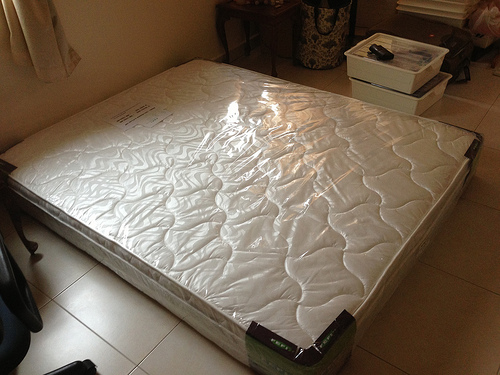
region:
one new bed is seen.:
[110, 125, 310, 238]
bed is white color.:
[160, 150, 315, 255]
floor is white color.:
[420, 290, 485, 340]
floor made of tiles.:
[46, 285, 126, 360]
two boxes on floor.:
[340, 36, 432, 109]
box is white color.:
[347, 40, 447, 105]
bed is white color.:
[166, 195, 341, 275]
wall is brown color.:
[85, 25, 165, 80]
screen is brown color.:
[11, 12, 54, 68]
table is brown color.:
[216, 23, 323, 62]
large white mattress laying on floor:
[65, 56, 475, 349]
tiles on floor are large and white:
[55, 266, 195, 364]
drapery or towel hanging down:
[0, 4, 106, 96]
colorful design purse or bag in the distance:
[289, 1, 358, 80]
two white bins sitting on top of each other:
[334, 27, 463, 126]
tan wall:
[49, 16, 145, 72]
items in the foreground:
[0, 266, 122, 369]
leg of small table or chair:
[7, 179, 76, 281]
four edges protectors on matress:
[202, 311, 385, 365]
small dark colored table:
[200, 4, 299, 79]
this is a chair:
[1, 247, 79, 372]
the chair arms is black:
[0, 235, 96, 373]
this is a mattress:
[17, 77, 471, 302]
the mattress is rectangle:
[61, 48, 426, 339]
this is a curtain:
[2, 1, 90, 80]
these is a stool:
[222, 2, 300, 67]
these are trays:
[344, 32, 462, 99]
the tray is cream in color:
[337, 35, 454, 95]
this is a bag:
[363, 10, 493, 52]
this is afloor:
[393, 285, 498, 367]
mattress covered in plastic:
[35, 61, 498, 318]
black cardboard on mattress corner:
[245, 306, 362, 371]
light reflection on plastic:
[217, 96, 286, 142]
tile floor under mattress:
[71, 258, 124, 333]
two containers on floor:
[344, 32, 460, 123]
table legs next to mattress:
[210, 9, 298, 73]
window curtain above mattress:
[25, 10, 77, 92]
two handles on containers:
[425, 57, 450, 99]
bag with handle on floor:
[285, 4, 353, 74]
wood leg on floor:
[7, 204, 44, 264]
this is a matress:
[56, 132, 384, 234]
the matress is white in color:
[43, 150, 423, 237]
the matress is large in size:
[58, 142, 385, 223]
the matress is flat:
[29, 130, 402, 205]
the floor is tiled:
[403, 272, 493, 372]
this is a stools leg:
[13, 209, 34, 256]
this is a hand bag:
[308, 11, 343, 60]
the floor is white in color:
[63, 305, 148, 328]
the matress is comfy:
[111, 129, 357, 231]